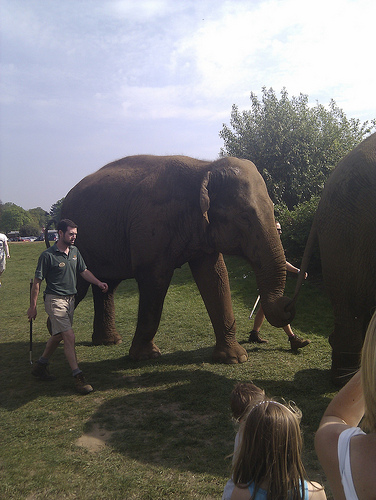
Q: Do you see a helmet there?
A: No, there are no helmets.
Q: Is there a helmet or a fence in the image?
A: No, there are no helmets or fences.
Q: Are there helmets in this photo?
A: No, there are no helmets.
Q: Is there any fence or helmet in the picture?
A: No, there are no helmets or fences.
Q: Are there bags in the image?
A: No, there are no bags.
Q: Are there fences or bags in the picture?
A: No, there are no bags or fences.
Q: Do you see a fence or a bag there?
A: No, there are no bags or fences.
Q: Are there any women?
A: Yes, there is a woman.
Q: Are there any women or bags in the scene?
A: Yes, there is a woman.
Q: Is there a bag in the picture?
A: No, there are no bags.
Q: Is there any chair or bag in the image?
A: No, there are no bags or chairs.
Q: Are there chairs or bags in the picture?
A: No, there are no bags or chairs.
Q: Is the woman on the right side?
A: Yes, the woman is on the right of the image.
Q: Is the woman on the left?
A: No, the woman is on the right of the image.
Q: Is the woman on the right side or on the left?
A: The woman is on the right of the image.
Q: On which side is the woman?
A: The woman is on the right of the image.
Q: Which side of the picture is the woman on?
A: The woman is on the right of the image.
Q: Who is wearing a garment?
A: The woman is wearing a garment.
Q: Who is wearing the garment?
A: The woman is wearing a garment.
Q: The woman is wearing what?
A: The woman is wearing a garment.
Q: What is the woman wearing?
A: The woman is wearing a garment.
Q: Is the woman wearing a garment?
A: Yes, the woman is wearing a garment.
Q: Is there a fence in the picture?
A: No, there are no fences.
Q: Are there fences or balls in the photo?
A: No, there are no fences or balls.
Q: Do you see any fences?
A: No, there are no fences.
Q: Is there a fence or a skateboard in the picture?
A: No, there are no fences or skateboards.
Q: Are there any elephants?
A: Yes, there is an elephant.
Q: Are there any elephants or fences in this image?
A: Yes, there is an elephant.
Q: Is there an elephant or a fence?
A: Yes, there is an elephant.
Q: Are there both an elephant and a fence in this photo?
A: No, there is an elephant but no fences.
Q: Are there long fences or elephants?
A: Yes, there is a long elephant.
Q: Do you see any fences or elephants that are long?
A: Yes, the elephant is long.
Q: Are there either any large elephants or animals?
A: Yes, there is a large elephant.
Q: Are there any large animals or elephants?
A: Yes, there is a large elephant.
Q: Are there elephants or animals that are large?
A: Yes, the elephant is large.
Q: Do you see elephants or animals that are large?
A: Yes, the elephant is large.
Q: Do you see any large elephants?
A: Yes, there is a large elephant.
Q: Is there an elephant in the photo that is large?
A: Yes, there is a large elephant.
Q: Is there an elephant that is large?
A: Yes, there is an elephant that is large.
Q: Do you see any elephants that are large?
A: Yes, there is an elephant that is large.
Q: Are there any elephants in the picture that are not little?
A: Yes, there is a large elephant.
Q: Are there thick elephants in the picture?
A: Yes, there is a thick elephant.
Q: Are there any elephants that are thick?
A: Yes, there is an elephant that is thick.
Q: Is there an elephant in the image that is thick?
A: Yes, there is an elephant that is thick.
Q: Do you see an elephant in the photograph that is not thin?
A: Yes, there is a thick elephant.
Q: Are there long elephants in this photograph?
A: Yes, there is a long elephant.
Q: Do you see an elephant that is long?
A: Yes, there is an elephant that is long.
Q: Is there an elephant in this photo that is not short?
A: Yes, there is a long elephant.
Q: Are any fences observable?
A: No, there are no fences.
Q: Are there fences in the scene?
A: No, there are no fences.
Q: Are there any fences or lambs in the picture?
A: No, there are no fences or lambs.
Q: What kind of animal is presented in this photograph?
A: The animal is an elephant.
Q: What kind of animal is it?
A: The animal is an elephant.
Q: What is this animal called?
A: This is an elephant.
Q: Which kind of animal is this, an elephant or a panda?
A: This is an elephant.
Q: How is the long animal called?
A: The animal is an elephant.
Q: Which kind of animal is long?
A: The animal is an elephant.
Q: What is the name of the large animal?
A: The animal is an elephant.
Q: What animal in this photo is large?
A: The animal is an elephant.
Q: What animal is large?
A: The animal is an elephant.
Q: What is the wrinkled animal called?
A: The animal is an elephant.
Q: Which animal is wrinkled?
A: The animal is an elephant.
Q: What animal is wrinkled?
A: The animal is an elephant.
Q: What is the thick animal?
A: The animal is an elephant.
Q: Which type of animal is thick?
A: The animal is an elephant.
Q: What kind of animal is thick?
A: The animal is an elephant.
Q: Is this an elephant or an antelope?
A: This is an elephant.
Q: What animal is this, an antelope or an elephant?
A: This is an elephant.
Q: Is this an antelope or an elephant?
A: This is an elephant.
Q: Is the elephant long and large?
A: Yes, the elephant is long and large.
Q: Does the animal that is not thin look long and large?
A: Yes, the elephant is long and large.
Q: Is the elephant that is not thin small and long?
A: No, the elephant is long but large.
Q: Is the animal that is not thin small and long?
A: No, the elephant is long but large.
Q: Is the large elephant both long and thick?
A: Yes, the elephant is long and thick.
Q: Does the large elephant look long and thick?
A: Yes, the elephant is long and thick.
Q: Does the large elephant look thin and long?
A: No, the elephant is long but thick.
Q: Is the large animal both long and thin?
A: No, the elephant is long but thick.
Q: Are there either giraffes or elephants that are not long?
A: No, there is an elephant but it is long.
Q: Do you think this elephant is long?
A: Yes, the elephant is long.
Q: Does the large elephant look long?
A: Yes, the elephant is long.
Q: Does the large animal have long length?
A: Yes, the elephant is long.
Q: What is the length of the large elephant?
A: The elephant is long.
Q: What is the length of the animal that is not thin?
A: The elephant is long.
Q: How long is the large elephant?
A: The elephant is long.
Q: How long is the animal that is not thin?
A: The elephant is long.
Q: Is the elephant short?
A: No, the elephant is long.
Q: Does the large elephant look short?
A: No, the elephant is long.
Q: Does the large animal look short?
A: No, the elephant is long.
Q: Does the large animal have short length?
A: No, the elephant is long.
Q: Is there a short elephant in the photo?
A: No, there is an elephant but it is long.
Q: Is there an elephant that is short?
A: No, there is an elephant but it is long.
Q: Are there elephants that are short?
A: No, there is an elephant but it is long.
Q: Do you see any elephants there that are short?
A: No, there is an elephant but it is long.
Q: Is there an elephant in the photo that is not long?
A: No, there is an elephant but it is long.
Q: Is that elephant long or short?
A: The elephant is long.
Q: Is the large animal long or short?
A: The elephant is long.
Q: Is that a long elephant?
A: Yes, that is a long elephant.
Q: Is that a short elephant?
A: No, that is a long elephant.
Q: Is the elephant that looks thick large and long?
A: Yes, the elephant is large and long.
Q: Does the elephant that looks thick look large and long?
A: Yes, the elephant is large and long.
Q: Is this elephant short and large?
A: No, the elephant is large but long.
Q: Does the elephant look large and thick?
A: Yes, the elephant is large and thick.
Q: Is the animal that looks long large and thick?
A: Yes, the elephant is large and thick.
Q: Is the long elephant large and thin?
A: No, the elephant is large but thick.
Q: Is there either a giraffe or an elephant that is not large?
A: No, there is an elephant but it is large.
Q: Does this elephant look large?
A: Yes, the elephant is large.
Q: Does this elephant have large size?
A: Yes, the elephant is large.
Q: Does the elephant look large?
A: Yes, the elephant is large.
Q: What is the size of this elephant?
A: The elephant is large.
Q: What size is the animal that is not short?
A: The elephant is large.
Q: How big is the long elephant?
A: The elephant is large.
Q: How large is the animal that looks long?
A: The elephant is large.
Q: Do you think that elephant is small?
A: No, the elephant is large.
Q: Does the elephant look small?
A: No, the elephant is large.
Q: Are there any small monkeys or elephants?
A: No, there is an elephant but it is large.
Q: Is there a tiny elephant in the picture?
A: No, there is an elephant but it is large.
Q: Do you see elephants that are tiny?
A: No, there is an elephant but it is large.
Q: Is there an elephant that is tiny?
A: No, there is an elephant but it is large.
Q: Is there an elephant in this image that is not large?
A: No, there is an elephant but it is large.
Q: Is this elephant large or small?
A: The elephant is large.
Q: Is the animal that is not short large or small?
A: The elephant is large.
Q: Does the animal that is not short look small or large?
A: The elephant is large.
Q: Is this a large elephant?
A: Yes, this is a large elephant.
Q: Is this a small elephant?
A: No, this is a large elephant.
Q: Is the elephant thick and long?
A: Yes, the elephant is thick and long.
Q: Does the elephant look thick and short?
A: No, the elephant is thick but long.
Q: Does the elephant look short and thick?
A: No, the elephant is thick but long.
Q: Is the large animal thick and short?
A: No, the elephant is thick but long.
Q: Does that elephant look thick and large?
A: Yes, the elephant is thick and large.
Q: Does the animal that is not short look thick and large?
A: Yes, the elephant is thick and large.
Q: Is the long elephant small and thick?
A: No, the elephant is thick but large.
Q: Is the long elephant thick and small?
A: No, the elephant is thick but large.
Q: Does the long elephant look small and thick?
A: No, the elephant is thick but large.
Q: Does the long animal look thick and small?
A: No, the elephant is thick but large.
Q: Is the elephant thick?
A: Yes, the elephant is thick.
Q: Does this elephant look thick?
A: Yes, the elephant is thick.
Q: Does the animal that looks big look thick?
A: Yes, the elephant is thick.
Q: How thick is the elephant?
A: The elephant is thick.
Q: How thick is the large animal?
A: The elephant is thick.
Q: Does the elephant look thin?
A: No, the elephant is thick.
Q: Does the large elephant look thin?
A: No, the elephant is thick.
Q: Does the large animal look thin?
A: No, the elephant is thick.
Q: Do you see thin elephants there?
A: No, there is an elephant but it is thick.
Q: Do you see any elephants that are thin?
A: No, there is an elephant but it is thick.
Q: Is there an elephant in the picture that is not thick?
A: No, there is an elephant but it is thick.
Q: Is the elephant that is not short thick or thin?
A: The elephant is thick.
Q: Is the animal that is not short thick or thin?
A: The elephant is thick.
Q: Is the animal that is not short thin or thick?
A: The elephant is thick.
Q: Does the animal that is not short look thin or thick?
A: The elephant is thick.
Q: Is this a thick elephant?
A: Yes, this is a thick elephant.